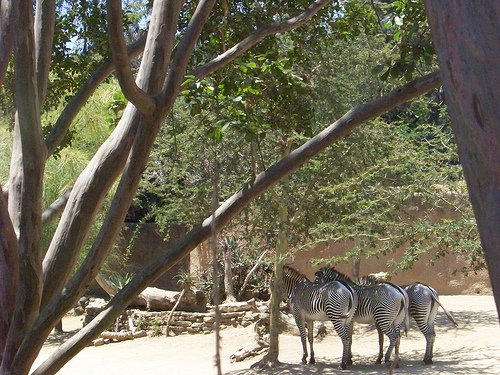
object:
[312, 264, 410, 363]
zebras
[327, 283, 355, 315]
butts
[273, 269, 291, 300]
head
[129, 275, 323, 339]
visible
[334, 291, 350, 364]
leg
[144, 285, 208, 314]
log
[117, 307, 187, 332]
wall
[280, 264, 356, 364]
group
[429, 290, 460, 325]
tails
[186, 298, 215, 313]
edge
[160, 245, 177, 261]
wood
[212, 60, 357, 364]
trees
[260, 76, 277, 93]
leaves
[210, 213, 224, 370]
stick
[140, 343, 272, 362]
ground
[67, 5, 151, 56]
sky